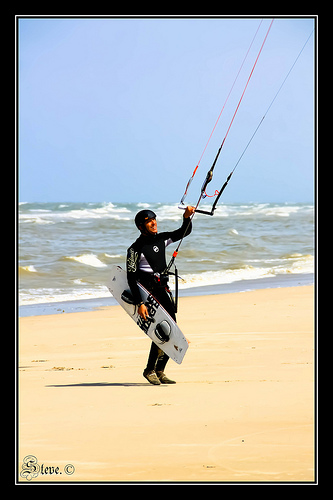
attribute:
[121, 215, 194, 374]
wetsuit — black, being worn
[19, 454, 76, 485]
copyright — black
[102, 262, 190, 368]
kiteboard — white, being held, connected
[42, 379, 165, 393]
shadow — black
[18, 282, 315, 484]
beach — sand, sandy, light brown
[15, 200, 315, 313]
ocean — green, choppy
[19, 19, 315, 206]
sky — blue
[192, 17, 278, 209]
cable — red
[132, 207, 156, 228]
helmet — black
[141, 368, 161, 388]
shoe — brown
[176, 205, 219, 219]
handle — for kiteboarding, black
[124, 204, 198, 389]
man — preparing, smiling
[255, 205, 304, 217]
wave — white capped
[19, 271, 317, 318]
sand — wet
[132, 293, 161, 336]
writing — black